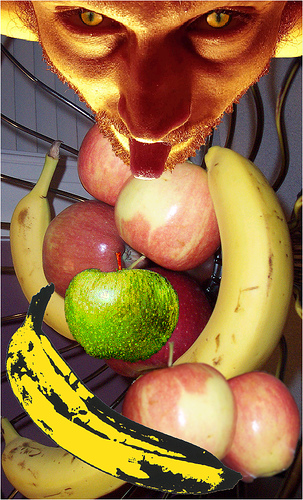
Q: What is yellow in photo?
A: Bananas.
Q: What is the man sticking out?
A: Tongue.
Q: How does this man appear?
A: Creepy.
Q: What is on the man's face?
A: A beard.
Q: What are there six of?
A: Red apples.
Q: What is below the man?
A: Fruit.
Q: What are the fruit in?
A: Metal basket.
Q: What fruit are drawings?
A: A banana and green apple.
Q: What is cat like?
A: Man's eyes.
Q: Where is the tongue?
A: On the man.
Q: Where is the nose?
A: On the human.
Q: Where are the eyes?
A: On the man.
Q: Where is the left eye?
A: On the man.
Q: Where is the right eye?
A: On the man.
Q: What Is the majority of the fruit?
A: Apples.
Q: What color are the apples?
A: Green, red, and yellow.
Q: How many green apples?
A: One.